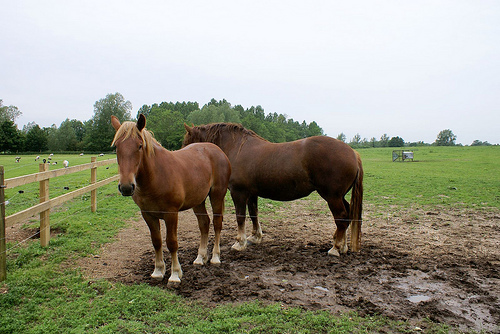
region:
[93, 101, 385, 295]
Two brown horses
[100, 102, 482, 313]
Two brown horses standing in the mud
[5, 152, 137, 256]
Brown wooden fence in the field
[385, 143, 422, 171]
Irrigation equipment in the field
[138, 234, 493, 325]
Muddy patch among the grass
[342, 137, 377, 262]
Horses' long tail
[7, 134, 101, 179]
Animals grazing in the pasture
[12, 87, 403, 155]
Wooden landscape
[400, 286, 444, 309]
Puddle of water in the mud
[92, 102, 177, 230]
Horse with a blonde mane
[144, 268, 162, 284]
front right hoof of the front horse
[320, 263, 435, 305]
part of a muddy ground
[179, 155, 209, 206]
stomach of a horse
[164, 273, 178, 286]
left hoof of the horse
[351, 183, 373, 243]
tail of the horse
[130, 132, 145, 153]
left eye of the horse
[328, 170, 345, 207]
left thigh of a horse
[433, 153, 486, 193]
part of a green ground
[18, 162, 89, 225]
part of a wooden fence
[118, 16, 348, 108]
part of the cloudy sky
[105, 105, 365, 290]
two brown horses on muddy ground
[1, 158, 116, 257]
wooden fences on grass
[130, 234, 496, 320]
muddy ground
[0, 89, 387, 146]
trees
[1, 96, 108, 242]
other animals on the other side of fence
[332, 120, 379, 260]
horse tail touching the muddy ground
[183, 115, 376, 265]
a darker colored horse standing behind a brown horse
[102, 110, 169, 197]
horse with gold hair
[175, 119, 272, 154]
horse with brown hair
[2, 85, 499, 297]
two horses in this side of the fence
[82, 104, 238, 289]
Horse in a corral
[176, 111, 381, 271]
Horse in a corral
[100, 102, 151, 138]
Large pointy ears of horse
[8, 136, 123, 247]
Fence of a corral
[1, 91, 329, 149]
Green trees in the background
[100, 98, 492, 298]
Horses stand in the mud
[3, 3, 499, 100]
Sky is cloudy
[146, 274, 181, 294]
Hooves are brown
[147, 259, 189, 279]
Front fetlocks are white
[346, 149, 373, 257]
Long tail of horse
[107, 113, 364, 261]
these are horses standing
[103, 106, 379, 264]
the horses are brown in color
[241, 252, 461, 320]
the place is muddy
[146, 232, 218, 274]
the horse has white legs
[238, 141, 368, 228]
this horse is fat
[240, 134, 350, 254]
this horse is short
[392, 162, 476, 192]
the grass are green in color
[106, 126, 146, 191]
the horse is staring at the camera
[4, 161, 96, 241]
a fence is beside the horses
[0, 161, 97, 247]
the fence is wooden